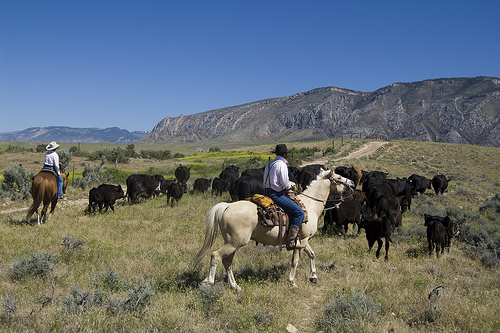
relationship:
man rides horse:
[250, 136, 302, 219] [190, 163, 360, 299]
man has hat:
[250, 136, 302, 219] [270, 139, 290, 160]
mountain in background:
[152, 74, 497, 147] [11, 9, 496, 148]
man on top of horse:
[250, 136, 302, 219] [190, 163, 360, 299]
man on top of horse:
[34, 134, 64, 178] [27, 165, 75, 229]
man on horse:
[250, 136, 302, 219] [190, 163, 360, 299]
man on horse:
[34, 134, 64, 178] [27, 165, 75, 229]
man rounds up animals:
[250, 136, 302, 219] [340, 160, 465, 265]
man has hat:
[34, 134, 64, 178] [45, 136, 59, 155]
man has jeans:
[250, 136, 302, 219] [270, 187, 306, 228]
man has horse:
[34, 134, 64, 178] [27, 165, 75, 229]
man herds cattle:
[250, 136, 302, 219] [88, 160, 462, 258]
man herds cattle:
[34, 134, 64, 178] [88, 160, 462, 258]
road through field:
[11, 180, 164, 218] [11, 152, 259, 328]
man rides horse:
[34, 134, 64, 178] [27, 165, 75, 229]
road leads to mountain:
[11, 180, 164, 218] [152, 74, 497, 147]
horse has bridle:
[190, 163, 360, 299] [331, 176, 356, 195]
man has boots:
[250, 136, 302, 219] [288, 221, 304, 257]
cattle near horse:
[88, 160, 462, 258] [190, 163, 360, 299]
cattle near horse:
[88, 160, 462, 258] [27, 165, 75, 229]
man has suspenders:
[250, 136, 302, 219] [261, 156, 276, 191]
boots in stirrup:
[288, 221, 304, 257] [283, 241, 301, 252]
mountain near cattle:
[152, 74, 497, 147] [88, 160, 462, 258]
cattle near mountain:
[88, 160, 462, 258] [152, 74, 497, 147]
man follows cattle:
[34, 134, 64, 178] [88, 160, 462, 258]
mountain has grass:
[152, 74, 497, 147] [394, 140, 492, 171]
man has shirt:
[250, 136, 302, 219] [261, 153, 295, 197]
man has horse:
[250, 136, 302, 219] [190, 163, 360, 299]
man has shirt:
[34, 134, 64, 178] [43, 150, 62, 170]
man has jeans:
[34, 134, 64, 178] [53, 172, 68, 203]